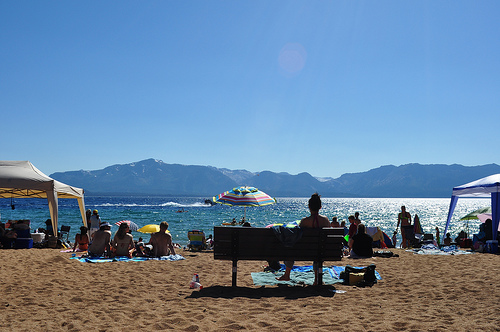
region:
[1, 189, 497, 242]
A large body of water.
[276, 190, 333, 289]
I woman relaxing on a bench.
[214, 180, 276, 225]
A large beach umbrella.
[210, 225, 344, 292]
A bench with a woman sitting on it.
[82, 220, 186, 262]
A group of people relaxing on a towel.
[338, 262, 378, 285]
A large bag sits on a towel.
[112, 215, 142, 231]
An American Flag designed umbrella.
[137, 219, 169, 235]
A yellow umbrella.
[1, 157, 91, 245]
A large canopy.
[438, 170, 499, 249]
Another large canopy with people under it.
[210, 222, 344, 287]
Back of a wood bench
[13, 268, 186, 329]
Sandy beach of footprints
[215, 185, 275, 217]
A multicolored stripe sun umbrella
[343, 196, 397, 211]
Sun glistening ocean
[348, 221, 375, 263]
Woman in a black shirt sitting on the sand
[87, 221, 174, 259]
Three people sitting on a blanket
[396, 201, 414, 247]
A woman in a bikini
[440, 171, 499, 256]
Blue and white canopy setup on the beach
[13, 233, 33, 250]
A blue ice chest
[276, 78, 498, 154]
Bright blue sky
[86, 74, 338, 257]
the sky is clear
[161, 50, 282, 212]
the sky is clear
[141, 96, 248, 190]
the sky is clear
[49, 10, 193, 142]
the sky is clear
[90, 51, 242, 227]
the sky is clear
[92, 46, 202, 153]
the sky is clear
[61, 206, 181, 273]
People lounging on the beach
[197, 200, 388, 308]
woman sitting on a bench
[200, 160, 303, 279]
Umbrella on the beach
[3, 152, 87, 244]
Large tent in the sand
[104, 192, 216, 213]
White cap wave in the ocean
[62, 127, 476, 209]
Mountains in the background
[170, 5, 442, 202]
Blue sky no clouds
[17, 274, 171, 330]
Footprints in the sand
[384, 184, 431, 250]
Woman wearing green bikini top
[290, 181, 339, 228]
Woman has hair in a bun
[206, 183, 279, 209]
BLUE, PINK, WHITE STRIPED UMBRELLA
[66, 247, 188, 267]
BLUE BEACH TOWELS ON SAND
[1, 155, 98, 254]
TAN EASY, UP TENT COVER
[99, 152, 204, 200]
MOUNTAINS ACROSS THE WATER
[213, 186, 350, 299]
WOMAN SITTING ON BENCH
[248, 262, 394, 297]
BLUE BEACH TOWELS ON THE SAND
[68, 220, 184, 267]
GROUP OF PEOPLE SITTING ON BEACH TOWELS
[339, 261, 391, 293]
BEACH BAG SITTING IN SAND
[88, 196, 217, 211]
WAVE COMING FROM BOAT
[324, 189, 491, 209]
REFLECTION OF SUN ON WATER